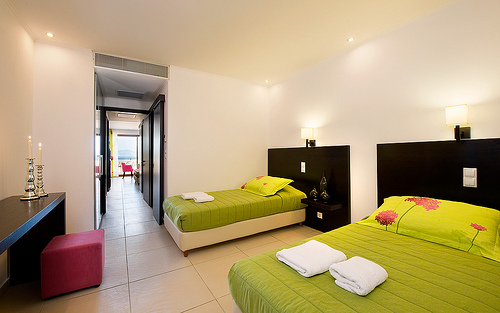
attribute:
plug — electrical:
[296, 159, 307, 174]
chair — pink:
[118, 158, 136, 178]